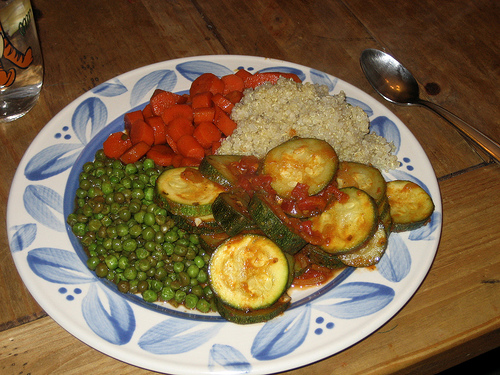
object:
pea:
[168, 227, 178, 242]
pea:
[136, 212, 146, 222]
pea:
[143, 188, 157, 202]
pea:
[88, 219, 100, 231]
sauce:
[235, 173, 312, 219]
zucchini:
[209, 231, 292, 311]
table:
[0, 0, 500, 375]